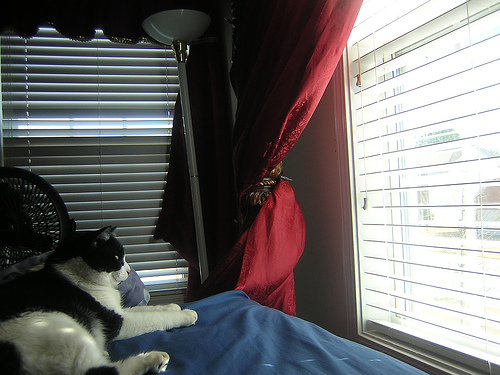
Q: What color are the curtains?
A: Red.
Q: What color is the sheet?
A: Blue.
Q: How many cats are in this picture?
A: One.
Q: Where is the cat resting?
A: On a bed.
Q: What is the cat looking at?
A: The window.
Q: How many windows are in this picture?
A: Two.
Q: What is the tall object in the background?
A: A lamp.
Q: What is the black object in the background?
A: A fan.